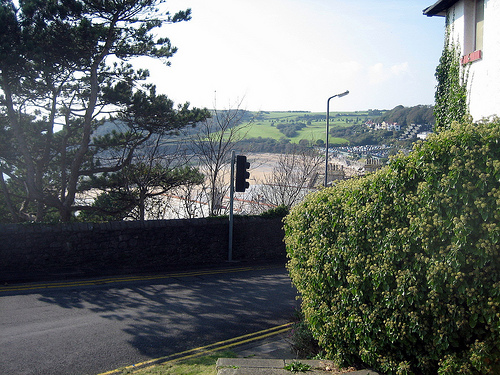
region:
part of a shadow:
[213, 299, 225, 311]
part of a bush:
[370, 244, 390, 264]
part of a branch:
[128, 204, 136, 213]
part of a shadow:
[165, 292, 180, 314]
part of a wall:
[66, 257, 95, 285]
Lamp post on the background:
[320, 87, 353, 188]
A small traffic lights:
[217, 146, 257, 261]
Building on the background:
[357, 115, 422, 140]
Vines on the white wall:
[429, 1, 499, 122]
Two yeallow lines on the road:
[111, 307, 309, 369]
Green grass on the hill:
[195, 100, 440, 152]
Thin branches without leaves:
[262, 145, 321, 198]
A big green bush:
[277, 109, 499, 364]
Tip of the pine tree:
[157, 6, 204, 26]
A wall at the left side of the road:
[2, 212, 289, 294]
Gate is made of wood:
[12, 215, 237, 279]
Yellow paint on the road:
[34, 273, 162, 293]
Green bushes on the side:
[253, 122, 498, 374]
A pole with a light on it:
[213, 133, 267, 275]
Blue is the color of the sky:
[221, 17, 296, 102]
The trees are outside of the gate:
[5, 5, 212, 225]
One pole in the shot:
[295, 72, 375, 209]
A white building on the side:
[467, 83, 490, 108]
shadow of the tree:
[179, 275, 272, 324]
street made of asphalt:
[28, 321, 113, 349]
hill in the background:
[200, 78, 312, 137]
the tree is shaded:
[1, 35, 135, 204]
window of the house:
[454, 3, 476, 63]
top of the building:
[325, 108, 392, 163]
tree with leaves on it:
[7, 5, 209, 230]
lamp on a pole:
[330, 85, 348, 100]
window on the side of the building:
[465, 3, 489, 63]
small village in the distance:
[353, 112, 405, 139]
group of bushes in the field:
[275, 118, 308, 143]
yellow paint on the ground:
[185, 328, 287, 354]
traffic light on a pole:
[231, 148, 254, 200]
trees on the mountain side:
[385, 100, 435, 125]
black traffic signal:
[231, 153, 249, 200]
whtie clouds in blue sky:
[218, 16, 244, 47]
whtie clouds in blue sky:
[295, 9, 312, 26]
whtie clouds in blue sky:
[338, 42, 368, 71]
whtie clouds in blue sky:
[375, 64, 402, 89]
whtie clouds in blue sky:
[235, 29, 269, 56]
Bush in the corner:
[281, 169, 491, 356]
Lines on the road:
[226, 324, 265, 352]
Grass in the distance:
[253, 120, 277, 137]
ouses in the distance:
[349, 117, 401, 138]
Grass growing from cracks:
[278, 354, 312, 372]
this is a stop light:
[213, 131, 269, 281]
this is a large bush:
[271, 131, 491, 367]